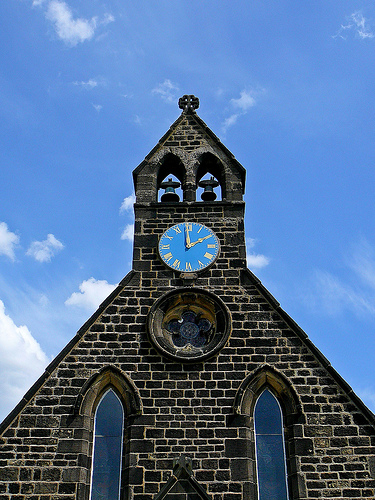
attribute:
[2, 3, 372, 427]
sky — blue, clear, pictured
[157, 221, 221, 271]
clock — blue, pictured, analog, yellow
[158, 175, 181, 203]
bell — pictured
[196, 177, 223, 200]
bell — pictured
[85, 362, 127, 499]
window — stain glass, pictured, stained glass, sunken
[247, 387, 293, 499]
window — stained glass, pictured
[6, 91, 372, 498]
building — brick, pictured, bricked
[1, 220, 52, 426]
cloud — fluffy, white, pictured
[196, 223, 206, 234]
roman numeral — gold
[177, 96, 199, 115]
steeple — round, decoration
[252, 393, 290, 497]
glass — pictured